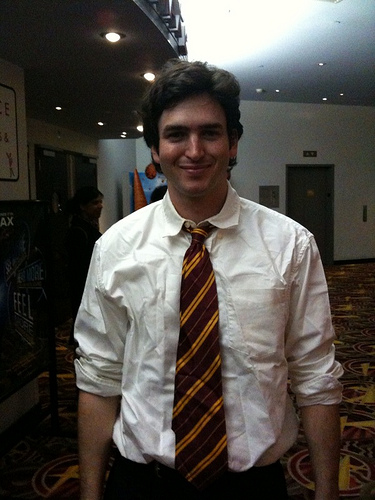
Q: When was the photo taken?
A: Day time.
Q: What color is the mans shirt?
A: White.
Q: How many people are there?
A: One.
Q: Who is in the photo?
A: A man.